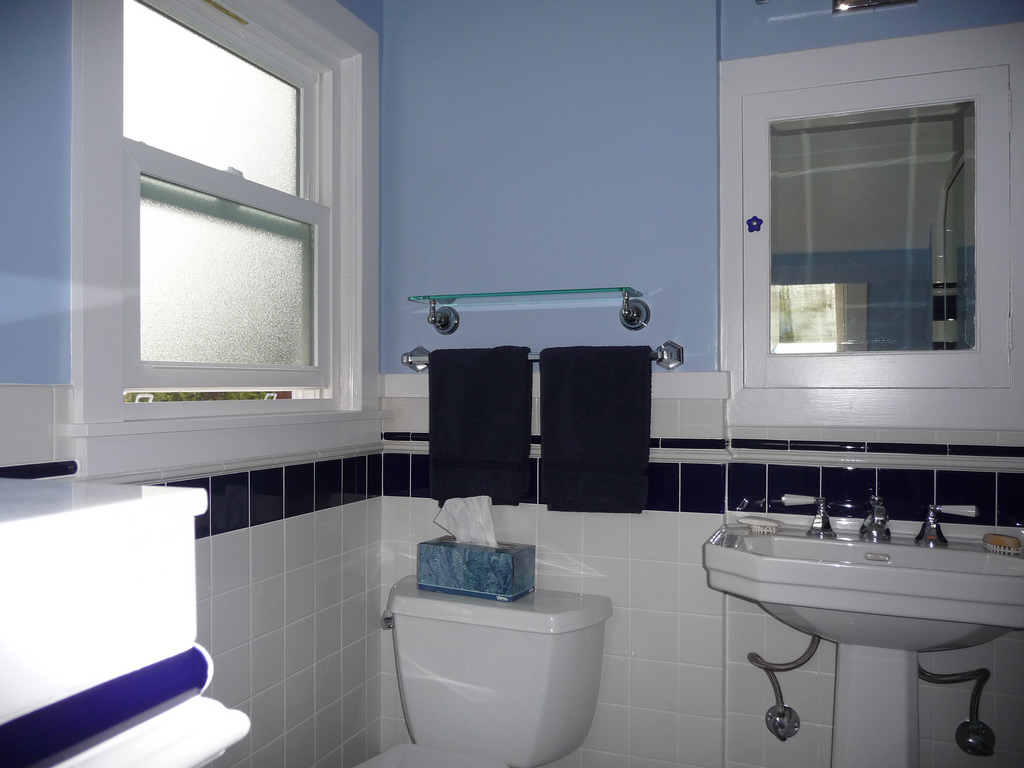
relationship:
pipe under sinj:
[744, 637, 824, 715] [702, 508, 1019, 766]